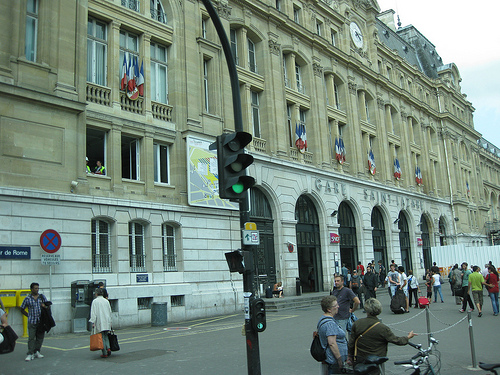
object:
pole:
[201, 2, 255, 374]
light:
[231, 181, 243, 195]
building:
[3, 2, 500, 342]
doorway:
[296, 246, 323, 294]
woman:
[89, 289, 121, 356]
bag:
[90, 332, 105, 349]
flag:
[296, 120, 308, 152]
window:
[252, 90, 262, 140]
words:
[314, 178, 347, 196]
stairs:
[264, 294, 331, 313]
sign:
[40, 226, 63, 254]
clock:
[347, 23, 365, 51]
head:
[94, 286, 104, 296]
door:
[296, 245, 320, 293]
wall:
[3, 0, 499, 330]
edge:
[0, 83, 88, 116]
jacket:
[89, 297, 112, 336]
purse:
[109, 331, 123, 353]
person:
[349, 293, 413, 375]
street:
[3, 280, 499, 374]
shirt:
[467, 272, 485, 292]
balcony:
[85, 81, 113, 108]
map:
[287, 243, 294, 254]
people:
[313, 295, 353, 374]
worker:
[95, 161, 107, 176]